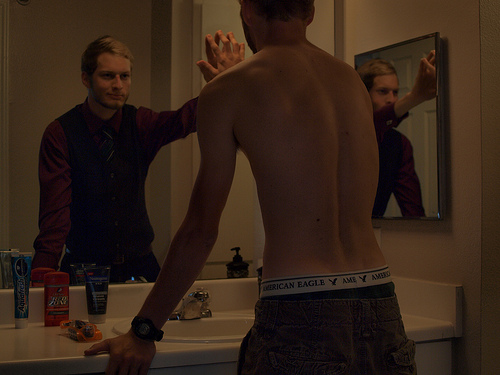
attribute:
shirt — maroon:
[9, 85, 211, 271]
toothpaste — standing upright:
[7, 244, 42, 331]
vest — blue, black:
[57, 103, 154, 263]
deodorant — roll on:
[41, 268, 71, 326]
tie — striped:
[96, 120, 121, 174]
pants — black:
[128, 250, 173, 282]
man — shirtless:
[140, 6, 398, 304]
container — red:
[44, 273, 69, 326]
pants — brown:
[233, 294, 417, 374]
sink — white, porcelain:
[102, 281, 277, 352]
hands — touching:
[188, 33, 243, 85]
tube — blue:
[7, 246, 32, 328]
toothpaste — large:
[10, 247, 33, 327]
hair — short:
[77, 30, 137, 65]